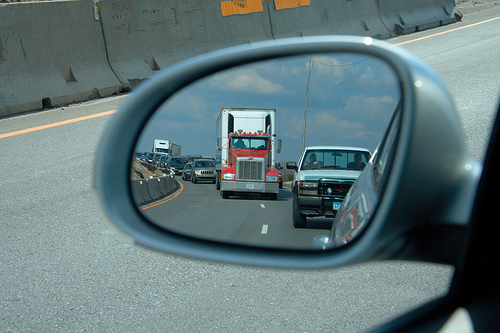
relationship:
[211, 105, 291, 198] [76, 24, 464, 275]
semi in mirror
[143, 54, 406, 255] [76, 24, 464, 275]
reflection in mirror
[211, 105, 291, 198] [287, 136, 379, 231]
semi behind car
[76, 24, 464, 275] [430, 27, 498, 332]
mirror on side of car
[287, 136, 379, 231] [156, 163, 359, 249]
car next to road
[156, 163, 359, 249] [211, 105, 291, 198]
road underneath semi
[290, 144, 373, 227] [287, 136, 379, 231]
car on car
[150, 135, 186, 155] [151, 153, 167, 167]
truck behind car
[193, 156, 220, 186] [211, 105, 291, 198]
car behind semi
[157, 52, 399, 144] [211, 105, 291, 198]
sky behind semi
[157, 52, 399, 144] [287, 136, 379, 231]
sky behind car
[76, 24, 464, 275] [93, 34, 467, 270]
mirror on side of mirror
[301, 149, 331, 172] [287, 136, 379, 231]
man in car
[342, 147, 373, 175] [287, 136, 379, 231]
man in car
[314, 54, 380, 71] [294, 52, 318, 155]
electrical wire on pole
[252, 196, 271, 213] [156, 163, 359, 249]
line on road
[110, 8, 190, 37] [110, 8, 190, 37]
graffiti on graffiti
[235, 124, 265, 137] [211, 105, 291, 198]
pipe on semi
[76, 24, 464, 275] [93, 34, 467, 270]
mirror on mirror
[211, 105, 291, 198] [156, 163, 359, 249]
semi on road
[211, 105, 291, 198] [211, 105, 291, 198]
semi on semi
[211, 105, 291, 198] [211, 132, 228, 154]
semi has front window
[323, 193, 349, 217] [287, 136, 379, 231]
radiator in front of car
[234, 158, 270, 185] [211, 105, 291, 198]
grill on semi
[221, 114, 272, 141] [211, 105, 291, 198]
smoke stack on semi